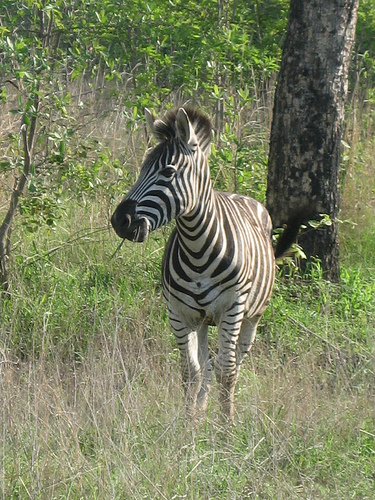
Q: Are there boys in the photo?
A: No, there are no boys.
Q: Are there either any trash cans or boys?
A: No, there are no boys or trash cans.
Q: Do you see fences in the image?
A: No, there are no fences.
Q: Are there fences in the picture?
A: No, there are no fences.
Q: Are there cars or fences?
A: No, there are no fences or cars.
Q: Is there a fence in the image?
A: No, there are no fences.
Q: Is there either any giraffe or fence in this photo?
A: No, there are no fences or giraffes.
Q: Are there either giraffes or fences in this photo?
A: No, there are no fences or giraffes.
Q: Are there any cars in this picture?
A: No, there are no cars.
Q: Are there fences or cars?
A: No, there are no cars or fences.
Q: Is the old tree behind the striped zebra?
A: Yes, the tree is behind the zebra.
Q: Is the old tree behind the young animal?
A: Yes, the tree is behind the zebra.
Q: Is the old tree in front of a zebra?
A: No, the tree is behind a zebra.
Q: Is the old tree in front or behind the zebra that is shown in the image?
A: The tree is behind the zebra.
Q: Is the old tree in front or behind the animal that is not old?
A: The tree is behind the zebra.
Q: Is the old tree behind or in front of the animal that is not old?
A: The tree is behind the zebra.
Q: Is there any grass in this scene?
A: Yes, there is grass.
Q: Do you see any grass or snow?
A: Yes, there is grass.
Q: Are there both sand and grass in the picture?
A: No, there is grass but no sand.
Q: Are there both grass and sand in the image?
A: No, there is grass but no sand.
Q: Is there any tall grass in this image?
A: Yes, there is tall grass.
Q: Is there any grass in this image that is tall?
A: Yes, there is grass that is tall.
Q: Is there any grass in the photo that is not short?
A: Yes, there is tall grass.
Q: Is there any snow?
A: No, there is no snow.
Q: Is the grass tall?
A: Yes, the grass is tall.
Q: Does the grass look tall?
A: Yes, the grass is tall.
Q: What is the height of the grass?
A: The grass is tall.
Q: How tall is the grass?
A: The grass is tall.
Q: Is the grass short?
A: No, the grass is tall.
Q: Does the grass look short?
A: No, the grass is tall.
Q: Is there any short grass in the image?
A: No, there is grass but it is tall.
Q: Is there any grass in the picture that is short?
A: No, there is grass but it is tall.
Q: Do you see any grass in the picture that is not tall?
A: No, there is grass but it is tall.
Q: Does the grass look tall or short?
A: The grass is tall.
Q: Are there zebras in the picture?
A: Yes, there is a zebra.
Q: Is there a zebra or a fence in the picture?
A: Yes, there is a zebra.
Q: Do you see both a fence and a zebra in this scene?
A: No, there is a zebra but no fences.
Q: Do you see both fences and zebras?
A: No, there is a zebra but no fences.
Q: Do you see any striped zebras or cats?
A: Yes, there is a striped zebra.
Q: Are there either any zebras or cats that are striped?
A: Yes, the zebra is striped.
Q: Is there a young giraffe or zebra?
A: Yes, there is a young zebra.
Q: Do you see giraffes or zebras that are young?
A: Yes, the zebra is young.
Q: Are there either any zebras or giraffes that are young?
A: Yes, the zebra is young.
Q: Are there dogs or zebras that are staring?
A: Yes, the zebra is staring.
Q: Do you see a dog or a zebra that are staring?
A: Yes, the zebra is staring.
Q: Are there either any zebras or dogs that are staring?
A: Yes, the zebra is staring.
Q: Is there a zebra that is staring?
A: Yes, there is a zebra that is staring.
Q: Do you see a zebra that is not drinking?
A: Yes, there is a zebra that is staring .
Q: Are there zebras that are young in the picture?
A: Yes, there is a young zebra.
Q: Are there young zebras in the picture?
A: Yes, there is a young zebra.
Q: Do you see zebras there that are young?
A: Yes, there is a zebra that is young.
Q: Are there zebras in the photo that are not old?
A: Yes, there is an young zebra.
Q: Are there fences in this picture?
A: No, there are no fences.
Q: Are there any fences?
A: No, there are no fences.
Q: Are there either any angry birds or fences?
A: No, there are no fences or angry birds.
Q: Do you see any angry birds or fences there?
A: No, there are no fences or angry birds.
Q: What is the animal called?
A: The animal is a zebra.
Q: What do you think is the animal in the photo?
A: The animal is a zebra.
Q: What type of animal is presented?
A: The animal is a zebra.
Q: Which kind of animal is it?
A: The animal is a zebra.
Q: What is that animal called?
A: This is a zebra.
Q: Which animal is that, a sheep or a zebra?
A: This is a zebra.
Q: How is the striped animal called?
A: The animal is a zebra.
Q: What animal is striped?
A: The animal is a zebra.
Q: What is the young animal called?
A: The animal is a zebra.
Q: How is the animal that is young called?
A: The animal is a zebra.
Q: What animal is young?
A: The animal is a zebra.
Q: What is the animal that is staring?
A: The animal is a zebra.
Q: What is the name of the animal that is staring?
A: The animal is a zebra.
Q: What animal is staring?
A: The animal is a zebra.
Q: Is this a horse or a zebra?
A: This is a zebra.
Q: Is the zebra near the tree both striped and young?
A: Yes, the zebra is striped and young.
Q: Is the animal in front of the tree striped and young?
A: Yes, the zebra is striped and young.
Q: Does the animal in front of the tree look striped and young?
A: Yes, the zebra is striped and young.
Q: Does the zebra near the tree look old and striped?
A: No, the zebra is striped but young.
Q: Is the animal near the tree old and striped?
A: No, the zebra is striped but young.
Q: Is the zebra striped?
A: Yes, the zebra is striped.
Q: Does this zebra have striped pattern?
A: Yes, the zebra is striped.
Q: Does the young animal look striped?
A: Yes, the zebra is striped.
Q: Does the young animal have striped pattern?
A: Yes, the zebra is striped.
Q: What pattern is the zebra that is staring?
A: The zebra is striped.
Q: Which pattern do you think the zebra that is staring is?
A: The zebra is striped.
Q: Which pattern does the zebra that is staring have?
A: The zebra has striped pattern.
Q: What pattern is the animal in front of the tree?
A: The zebra is striped.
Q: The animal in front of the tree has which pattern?
A: The zebra is striped.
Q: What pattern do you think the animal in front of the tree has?
A: The zebra has striped pattern.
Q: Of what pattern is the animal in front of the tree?
A: The zebra is striped.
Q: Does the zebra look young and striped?
A: Yes, the zebra is young and striped.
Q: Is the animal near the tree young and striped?
A: Yes, the zebra is young and striped.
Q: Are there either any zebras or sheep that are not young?
A: No, there is a zebra but it is young.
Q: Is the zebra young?
A: Yes, the zebra is young.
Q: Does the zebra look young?
A: Yes, the zebra is young.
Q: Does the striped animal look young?
A: Yes, the zebra is young.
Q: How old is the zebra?
A: The zebra is young.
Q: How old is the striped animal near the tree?
A: The zebra is young.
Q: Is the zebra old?
A: No, the zebra is young.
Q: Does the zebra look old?
A: No, the zebra is young.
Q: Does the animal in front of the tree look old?
A: No, the zebra is young.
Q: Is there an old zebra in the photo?
A: No, there is a zebra but it is young.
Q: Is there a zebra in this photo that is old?
A: No, there is a zebra but it is young.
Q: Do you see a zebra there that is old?
A: No, there is a zebra but it is young.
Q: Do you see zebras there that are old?
A: No, there is a zebra but it is young.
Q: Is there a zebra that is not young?
A: No, there is a zebra but it is young.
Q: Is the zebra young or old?
A: The zebra is young.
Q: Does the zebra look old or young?
A: The zebra is young.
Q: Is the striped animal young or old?
A: The zebra is young.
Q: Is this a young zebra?
A: Yes, this is a young zebra.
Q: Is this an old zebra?
A: No, this is a young zebra.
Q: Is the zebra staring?
A: Yes, the zebra is staring.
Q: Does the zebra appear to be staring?
A: Yes, the zebra is staring.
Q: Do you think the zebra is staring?
A: Yes, the zebra is staring.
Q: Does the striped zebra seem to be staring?
A: Yes, the zebra is staring.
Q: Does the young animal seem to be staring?
A: Yes, the zebra is staring.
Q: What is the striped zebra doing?
A: The zebra is staring.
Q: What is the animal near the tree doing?
A: The zebra is staring.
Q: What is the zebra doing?
A: The zebra is staring.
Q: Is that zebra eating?
A: No, the zebra is staring.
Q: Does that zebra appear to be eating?
A: No, the zebra is staring.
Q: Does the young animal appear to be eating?
A: No, the zebra is staring.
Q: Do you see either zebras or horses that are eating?
A: No, there is a zebra but it is staring.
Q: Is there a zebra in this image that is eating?
A: No, there is a zebra but it is staring.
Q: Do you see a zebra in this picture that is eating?
A: No, there is a zebra but it is staring.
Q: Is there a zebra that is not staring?
A: No, there is a zebra but it is staring.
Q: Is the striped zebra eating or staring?
A: The zebra is staring.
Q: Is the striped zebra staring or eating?
A: The zebra is staring.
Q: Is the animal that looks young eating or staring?
A: The zebra is staring.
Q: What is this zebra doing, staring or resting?
A: The zebra is staring.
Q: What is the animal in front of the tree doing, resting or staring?
A: The zebra is staring.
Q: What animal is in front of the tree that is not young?
A: The zebra is in front of the tree.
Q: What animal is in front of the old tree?
A: The animal is a zebra.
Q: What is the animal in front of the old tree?
A: The animal is a zebra.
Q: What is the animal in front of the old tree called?
A: The animal is a zebra.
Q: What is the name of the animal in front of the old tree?
A: The animal is a zebra.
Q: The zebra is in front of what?
A: The zebra is in front of the tree.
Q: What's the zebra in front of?
A: The zebra is in front of the tree.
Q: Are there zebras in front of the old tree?
A: Yes, there is a zebra in front of the tree.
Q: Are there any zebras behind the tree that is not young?
A: No, the zebra is in front of the tree.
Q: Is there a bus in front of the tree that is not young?
A: No, there is a zebra in front of the tree.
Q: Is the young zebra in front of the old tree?
A: Yes, the zebra is in front of the tree.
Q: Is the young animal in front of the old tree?
A: Yes, the zebra is in front of the tree.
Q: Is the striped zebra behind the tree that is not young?
A: No, the zebra is in front of the tree.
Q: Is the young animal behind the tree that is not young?
A: No, the zebra is in front of the tree.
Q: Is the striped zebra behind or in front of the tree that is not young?
A: The zebra is in front of the tree.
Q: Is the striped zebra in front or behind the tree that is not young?
A: The zebra is in front of the tree.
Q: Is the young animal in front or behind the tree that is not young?
A: The zebra is in front of the tree.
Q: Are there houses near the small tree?
A: No, there is a zebra near the tree.